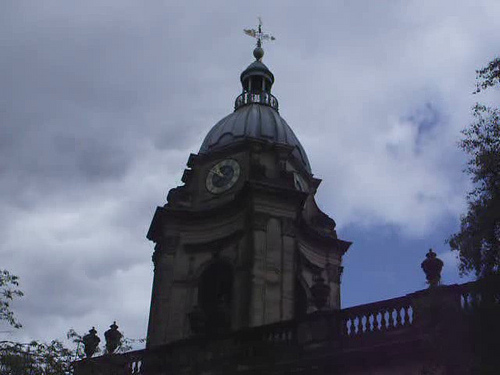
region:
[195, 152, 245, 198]
roman letter clock in the building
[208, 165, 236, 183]
two needles in the clock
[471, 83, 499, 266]
leaves and branches of the tree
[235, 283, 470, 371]
design in the building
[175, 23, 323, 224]
top of the building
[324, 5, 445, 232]
skies with clouds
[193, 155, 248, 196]
white and black color background of the building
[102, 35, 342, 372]
big old building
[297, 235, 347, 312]
design of the building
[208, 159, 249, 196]
two needle in the roman letter clock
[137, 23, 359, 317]
tower on an old building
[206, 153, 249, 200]
clock on the tower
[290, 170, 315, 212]
clock on the tower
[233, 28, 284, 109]
turret on the tower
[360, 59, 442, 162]
clouds in the sky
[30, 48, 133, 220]
clouds in the sky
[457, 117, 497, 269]
leaves on the trees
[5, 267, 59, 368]
leaves on the trees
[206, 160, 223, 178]
hands on the clock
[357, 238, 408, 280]
blue sky next to tower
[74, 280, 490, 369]
decorative holes in the top of a wall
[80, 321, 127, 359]
two decorations on the top of a wall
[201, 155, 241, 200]
round clock on one side of a steeple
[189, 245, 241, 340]
bell chamber in a steeple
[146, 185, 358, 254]
fancy woodwork around a steeple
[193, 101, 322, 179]
dome top roof portion of a steeple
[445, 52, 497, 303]
tree near a dark old church building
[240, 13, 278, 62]
weather vane at the top of a church steeple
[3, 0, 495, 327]
mostly dark cloudy sky with some blue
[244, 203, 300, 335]
stone work in the church steeple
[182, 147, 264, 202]
a clock on a building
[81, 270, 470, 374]
a cement railing in front of building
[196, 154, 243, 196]
a white area on the clock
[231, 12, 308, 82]
a cross on top of building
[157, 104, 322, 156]
a dome on the building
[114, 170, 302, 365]
a rounded out section of building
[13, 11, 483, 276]
white clouds in the sky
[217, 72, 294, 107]
an are to stand on top of dome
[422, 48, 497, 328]
a tree on the right side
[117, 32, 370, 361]
an old building with clock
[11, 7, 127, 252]
gray stormy looking clouds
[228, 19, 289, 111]
weather vein is pointing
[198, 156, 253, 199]
round designed clock time is 10:48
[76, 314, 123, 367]
two urn style vase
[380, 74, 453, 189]
white clouds witha blue center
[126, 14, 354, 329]
design of tower is interesting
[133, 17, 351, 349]
interesting designs are in this building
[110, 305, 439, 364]
block design railing in front of building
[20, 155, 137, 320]
several layers of white fluffy clouds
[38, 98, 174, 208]
mysterious shapes in the clouds